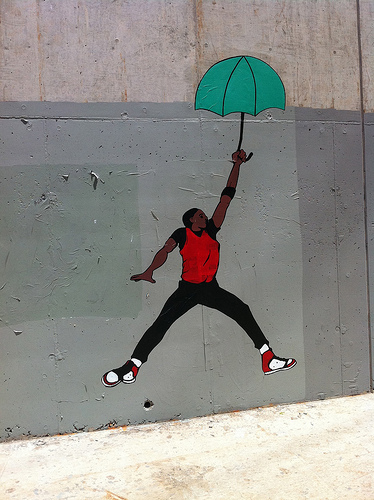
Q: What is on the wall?
A: Art.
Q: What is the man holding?
A: Umbrella.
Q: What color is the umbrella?
A: Green.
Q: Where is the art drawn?
A: On a wall.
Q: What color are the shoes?
A: Red and white.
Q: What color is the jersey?
A: Red.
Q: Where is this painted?
A: On a building.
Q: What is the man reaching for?
A: Umbrella.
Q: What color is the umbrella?
A: Green.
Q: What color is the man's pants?
A: Black.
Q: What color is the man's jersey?
A: Red.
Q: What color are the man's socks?
A: White.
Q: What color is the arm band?
A: Black.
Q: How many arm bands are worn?
A: One.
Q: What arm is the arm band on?
A: The left.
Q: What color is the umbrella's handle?
A: Black.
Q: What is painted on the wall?
A: A man.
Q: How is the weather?
A: Sunny.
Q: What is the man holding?
A: An umbrellas.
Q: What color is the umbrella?
A: Green.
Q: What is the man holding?
A: A green umbrella.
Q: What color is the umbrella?
A: Green.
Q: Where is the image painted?
A: On the wall.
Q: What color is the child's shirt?
A: Red.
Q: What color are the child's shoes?
A: Red, white, and black.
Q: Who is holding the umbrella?
A: The black child.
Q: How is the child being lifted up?
A: By the umbrella.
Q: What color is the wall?
A: Grey.